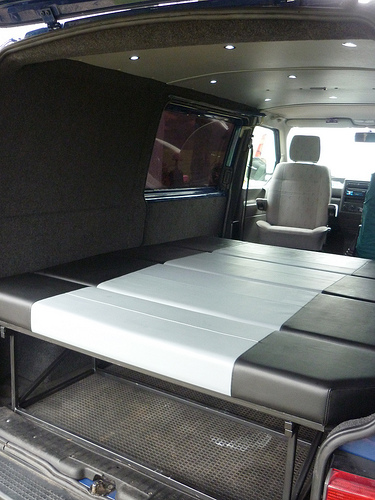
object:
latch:
[90, 477, 115, 497]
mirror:
[354, 131, 375, 142]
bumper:
[0, 452, 81, 499]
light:
[341, 41, 357, 48]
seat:
[255, 134, 339, 250]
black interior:
[0, 1, 374, 495]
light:
[321, 466, 374, 499]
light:
[344, 188, 352, 195]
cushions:
[0, 235, 375, 425]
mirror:
[144, 99, 243, 191]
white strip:
[30, 237, 369, 397]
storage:
[0, 329, 317, 498]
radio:
[344, 180, 369, 199]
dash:
[339, 180, 371, 215]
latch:
[37, 7, 62, 32]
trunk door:
[1, 0, 168, 31]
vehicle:
[1, 53, 373, 499]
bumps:
[21, 365, 328, 499]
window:
[286, 125, 375, 182]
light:
[224, 43, 236, 50]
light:
[128, 54, 139, 61]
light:
[288, 74, 296, 79]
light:
[210, 79, 217, 84]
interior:
[1, 23, 367, 479]